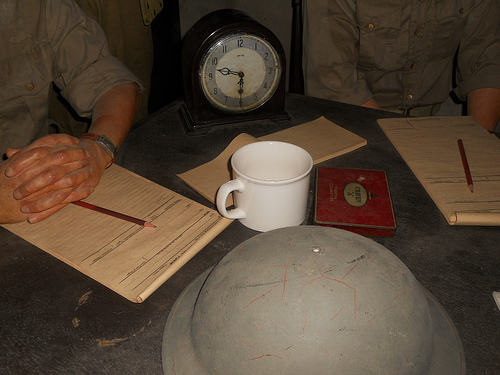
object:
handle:
[216, 179, 245, 219]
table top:
[1, 270, 162, 374]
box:
[313, 167, 397, 237]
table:
[0, 92, 497, 375]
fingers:
[4, 133, 94, 223]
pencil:
[70, 200, 157, 227]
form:
[0, 163, 236, 304]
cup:
[216, 141, 314, 233]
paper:
[375, 115, 500, 226]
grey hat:
[161, 224, 466, 375]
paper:
[176, 115, 367, 209]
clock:
[177, 9, 295, 136]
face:
[201, 34, 282, 113]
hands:
[0, 129, 104, 228]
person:
[301, 0, 499, 132]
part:
[353, 280, 369, 292]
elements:
[312, 245, 320, 253]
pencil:
[456, 139, 475, 193]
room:
[0, 4, 497, 375]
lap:
[450, 75, 499, 100]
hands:
[380, 118, 415, 129]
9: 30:
[208, 67, 244, 106]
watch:
[78, 133, 118, 169]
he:
[0, 0, 145, 227]